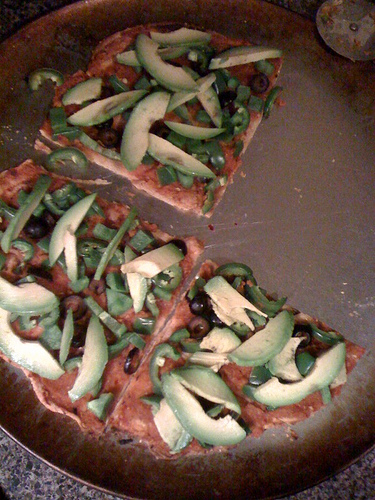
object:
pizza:
[35, 23, 287, 221]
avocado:
[132, 32, 202, 94]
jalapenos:
[25, 65, 67, 93]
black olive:
[247, 73, 272, 96]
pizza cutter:
[315, 1, 374, 61]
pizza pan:
[1, 1, 373, 499]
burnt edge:
[0, 362, 374, 500]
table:
[0, 1, 324, 46]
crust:
[44, 18, 277, 133]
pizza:
[0, 159, 364, 463]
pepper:
[214, 262, 254, 278]